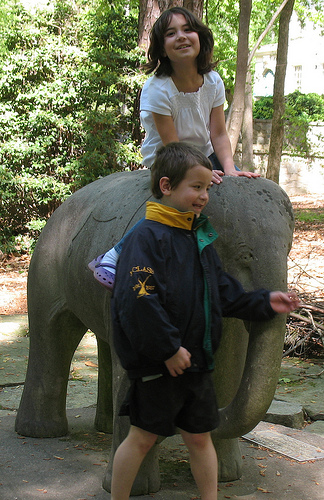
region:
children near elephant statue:
[14, 5, 313, 491]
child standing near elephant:
[106, 159, 297, 488]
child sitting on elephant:
[139, 7, 259, 174]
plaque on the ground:
[234, 431, 322, 467]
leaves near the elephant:
[54, 443, 110, 471]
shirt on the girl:
[127, 66, 225, 151]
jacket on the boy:
[113, 208, 210, 364]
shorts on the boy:
[108, 368, 226, 431]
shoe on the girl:
[93, 257, 119, 281]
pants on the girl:
[115, 214, 134, 251]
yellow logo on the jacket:
[126, 262, 157, 297]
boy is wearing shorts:
[118, 362, 221, 439]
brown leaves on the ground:
[243, 439, 294, 466]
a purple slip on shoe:
[85, 253, 116, 286]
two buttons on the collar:
[196, 232, 211, 247]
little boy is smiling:
[153, 147, 210, 213]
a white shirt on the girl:
[140, 72, 227, 159]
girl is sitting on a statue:
[92, 8, 250, 274]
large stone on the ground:
[270, 400, 305, 429]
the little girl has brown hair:
[142, 7, 218, 75]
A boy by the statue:
[135, 150, 274, 466]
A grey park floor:
[14, 455, 48, 497]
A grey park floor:
[56, 437, 99, 478]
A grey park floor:
[240, 446, 293, 496]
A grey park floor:
[299, 426, 322, 497]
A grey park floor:
[1, 352, 27, 411]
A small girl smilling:
[135, 7, 236, 150]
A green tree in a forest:
[76, 47, 137, 171]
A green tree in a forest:
[12, 96, 93, 208]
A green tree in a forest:
[260, 79, 322, 116]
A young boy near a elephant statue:
[130, 142, 258, 347]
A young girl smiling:
[140, 9, 237, 139]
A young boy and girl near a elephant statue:
[40, 8, 303, 344]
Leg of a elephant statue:
[14, 319, 76, 440]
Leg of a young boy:
[113, 434, 144, 496]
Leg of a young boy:
[181, 436, 226, 498]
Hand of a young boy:
[167, 343, 194, 376]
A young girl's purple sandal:
[87, 253, 111, 285]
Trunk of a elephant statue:
[238, 337, 285, 427]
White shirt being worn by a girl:
[148, 77, 223, 143]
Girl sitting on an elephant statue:
[15, 3, 295, 494]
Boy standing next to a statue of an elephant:
[15, 141, 298, 499]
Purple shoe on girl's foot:
[86, 248, 116, 289]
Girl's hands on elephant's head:
[205, 164, 260, 187]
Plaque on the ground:
[242, 424, 322, 462]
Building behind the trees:
[249, 11, 322, 107]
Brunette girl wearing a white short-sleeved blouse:
[138, 5, 234, 173]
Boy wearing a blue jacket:
[110, 138, 293, 380]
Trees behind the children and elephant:
[0, 2, 323, 246]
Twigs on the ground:
[286, 294, 322, 352]